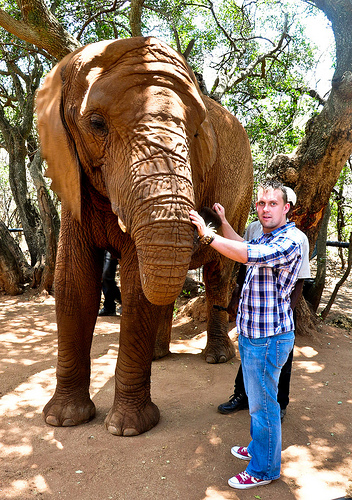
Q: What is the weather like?
A: It is clear.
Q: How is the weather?
A: It is clear.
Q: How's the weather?
A: It is clear.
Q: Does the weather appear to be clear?
A: Yes, it is clear.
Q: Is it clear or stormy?
A: It is clear.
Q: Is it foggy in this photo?
A: No, it is clear.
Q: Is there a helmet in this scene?
A: No, there are no helmets.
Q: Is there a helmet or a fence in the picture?
A: No, there are no helmets or fences.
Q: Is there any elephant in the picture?
A: Yes, there is an elephant.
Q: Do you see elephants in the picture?
A: Yes, there is an elephant.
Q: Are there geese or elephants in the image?
A: Yes, there is an elephant.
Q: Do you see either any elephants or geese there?
A: Yes, there is an elephant.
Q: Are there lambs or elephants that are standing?
A: Yes, the elephant is standing.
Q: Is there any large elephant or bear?
A: Yes, there is a large elephant.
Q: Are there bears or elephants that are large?
A: Yes, the elephant is large.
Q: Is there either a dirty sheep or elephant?
A: Yes, there is a dirty elephant.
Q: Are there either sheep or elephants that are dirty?
A: Yes, the elephant is dirty.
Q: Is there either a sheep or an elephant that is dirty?
A: Yes, the elephant is dirty.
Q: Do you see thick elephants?
A: Yes, there is a thick elephant.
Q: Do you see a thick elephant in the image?
A: Yes, there is a thick elephant.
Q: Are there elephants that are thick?
A: Yes, there is an elephant that is thick.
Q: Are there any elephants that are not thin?
A: Yes, there is a thick elephant.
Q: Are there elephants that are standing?
A: Yes, there is an elephant that is standing.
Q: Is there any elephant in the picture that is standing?
A: Yes, there is an elephant that is standing.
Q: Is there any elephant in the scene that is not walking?
A: Yes, there is an elephant that is standing.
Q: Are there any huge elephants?
A: Yes, there is a huge elephant.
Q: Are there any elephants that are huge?
A: Yes, there is an elephant that is huge.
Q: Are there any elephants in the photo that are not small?
A: Yes, there is a huge elephant.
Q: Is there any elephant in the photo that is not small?
A: Yes, there is a huge elephant.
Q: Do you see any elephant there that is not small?
A: Yes, there is a huge elephant.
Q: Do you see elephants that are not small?
A: Yes, there is a huge elephant.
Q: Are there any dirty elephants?
A: Yes, there is a dirty elephant.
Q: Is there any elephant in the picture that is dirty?
A: Yes, there is an elephant that is dirty.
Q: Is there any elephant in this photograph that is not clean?
A: Yes, there is a dirty elephant.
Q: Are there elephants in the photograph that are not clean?
A: Yes, there is a dirty elephant.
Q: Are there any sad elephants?
A: Yes, there is a sad elephant.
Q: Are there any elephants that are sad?
A: Yes, there is an elephant that is sad.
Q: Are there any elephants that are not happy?
A: Yes, there is a sad elephant.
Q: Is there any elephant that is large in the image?
A: Yes, there is a large elephant.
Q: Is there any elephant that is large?
A: Yes, there is an elephant that is large.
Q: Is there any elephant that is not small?
A: Yes, there is a large elephant.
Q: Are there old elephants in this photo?
A: Yes, there is an old elephant.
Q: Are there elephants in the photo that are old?
A: Yes, there is an elephant that is old.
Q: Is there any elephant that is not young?
A: Yes, there is a old elephant.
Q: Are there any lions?
A: No, there are no lions.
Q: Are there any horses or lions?
A: No, there are no lions or horses.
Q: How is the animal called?
A: The animal is an elephant.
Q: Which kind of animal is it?
A: The animal is an elephant.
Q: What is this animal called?
A: This is an elephant.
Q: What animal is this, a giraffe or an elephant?
A: This is an elephant.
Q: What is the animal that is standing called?
A: The animal is an elephant.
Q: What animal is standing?
A: The animal is an elephant.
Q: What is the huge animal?
A: The animal is an elephant.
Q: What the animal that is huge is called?
A: The animal is an elephant.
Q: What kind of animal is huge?
A: The animal is an elephant.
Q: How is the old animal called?
A: The animal is an elephant.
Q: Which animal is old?
A: The animal is an elephant.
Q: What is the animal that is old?
A: The animal is an elephant.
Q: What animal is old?
A: The animal is an elephant.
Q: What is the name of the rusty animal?
A: The animal is an elephant.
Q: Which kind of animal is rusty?
A: The animal is an elephant.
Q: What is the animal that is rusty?
A: The animal is an elephant.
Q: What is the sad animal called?
A: The animal is an elephant.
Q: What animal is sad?
A: The animal is an elephant.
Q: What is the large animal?
A: The animal is an elephant.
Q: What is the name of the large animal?
A: The animal is an elephant.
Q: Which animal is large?
A: The animal is an elephant.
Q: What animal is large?
A: The animal is an elephant.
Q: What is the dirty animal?
A: The animal is an elephant.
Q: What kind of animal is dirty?
A: The animal is an elephant.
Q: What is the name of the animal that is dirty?
A: The animal is an elephant.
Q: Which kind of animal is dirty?
A: The animal is an elephant.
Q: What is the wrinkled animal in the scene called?
A: The animal is an elephant.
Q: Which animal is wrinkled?
A: The animal is an elephant.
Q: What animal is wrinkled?
A: The animal is an elephant.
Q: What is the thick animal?
A: The animal is an elephant.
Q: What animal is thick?
A: The animal is an elephant.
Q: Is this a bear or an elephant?
A: This is an elephant.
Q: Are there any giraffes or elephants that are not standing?
A: No, there is an elephant but it is standing.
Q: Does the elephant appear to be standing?
A: Yes, the elephant is standing.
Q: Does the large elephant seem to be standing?
A: Yes, the elephant is standing.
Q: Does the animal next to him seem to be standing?
A: Yes, the elephant is standing.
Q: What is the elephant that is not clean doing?
A: The elephant is standing.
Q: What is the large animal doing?
A: The elephant is standing.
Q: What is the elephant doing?
A: The elephant is standing.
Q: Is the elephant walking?
A: No, the elephant is standing.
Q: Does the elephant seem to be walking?
A: No, the elephant is standing.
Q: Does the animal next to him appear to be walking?
A: No, the elephant is standing.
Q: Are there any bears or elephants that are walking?
A: No, there is an elephant but it is standing.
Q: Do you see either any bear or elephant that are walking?
A: No, there is an elephant but it is standing.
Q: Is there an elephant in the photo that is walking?
A: No, there is an elephant but it is standing.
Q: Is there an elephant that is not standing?
A: No, there is an elephant but it is standing.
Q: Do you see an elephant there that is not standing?
A: No, there is an elephant but it is standing.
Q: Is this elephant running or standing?
A: The elephant is standing.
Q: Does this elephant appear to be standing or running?
A: The elephant is standing.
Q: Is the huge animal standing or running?
A: The elephant is standing.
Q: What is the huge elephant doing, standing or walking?
A: The elephant is standing.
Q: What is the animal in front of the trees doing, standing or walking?
A: The elephant is standing.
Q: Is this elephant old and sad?
A: Yes, the elephant is old and sad.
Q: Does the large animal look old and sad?
A: Yes, the elephant is old and sad.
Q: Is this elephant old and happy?
A: No, the elephant is old but sad.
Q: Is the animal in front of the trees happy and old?
A: No, the elephant is old but sad.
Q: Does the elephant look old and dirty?
A: Yes, the elephant is old and dirty.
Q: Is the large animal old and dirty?
A: Yes, the elephant is old and dirty.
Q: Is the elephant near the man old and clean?
A: No, the elephant is old but dirty.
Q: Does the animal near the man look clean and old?
A: No, the elephant is old but dirty.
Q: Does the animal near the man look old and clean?
A: No, the elephant is old but dirty.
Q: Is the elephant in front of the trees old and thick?
A: Yes, the elephant is old and thick.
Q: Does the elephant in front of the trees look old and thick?
A: Yes, the elephant is old and thick.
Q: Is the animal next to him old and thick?
A: Yes, the elephant is old and thick.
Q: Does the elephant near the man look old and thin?
A: No, the elephant is old but thick.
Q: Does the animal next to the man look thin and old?
A: No, the elephant is old but thick.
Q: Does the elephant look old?
A: Yes, the elephant is old.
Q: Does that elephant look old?
A: Yes, the elephant is old.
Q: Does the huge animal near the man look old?
A: Yes, the elephant is old.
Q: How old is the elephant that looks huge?
A: The elephant is old.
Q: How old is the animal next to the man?
A: The elephant is old.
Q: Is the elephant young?
A: No, the elephant is old.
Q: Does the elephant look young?
A: No, the elephant is old.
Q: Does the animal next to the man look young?
A: No, the elephant is old.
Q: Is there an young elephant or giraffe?
A: No, there is an elephant but it is old.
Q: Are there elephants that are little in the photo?
A: No, there is an elephant but it is old.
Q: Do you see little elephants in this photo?
A: No, there is an elephant but it is old.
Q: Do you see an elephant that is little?
A: No, there is an elephant but it is old.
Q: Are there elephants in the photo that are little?
A: No, there is an elephant but it is old.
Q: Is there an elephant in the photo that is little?
A: No, there is an elephant but it is old.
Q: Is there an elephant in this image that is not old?
A: No, there is an elephant but it is old.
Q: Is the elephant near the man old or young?
A: The elephant is old.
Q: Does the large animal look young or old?
A: The elephant is old.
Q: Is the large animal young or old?
A: The elephant is old.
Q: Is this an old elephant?
A: Yes, this is an old elephant.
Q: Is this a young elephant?
A: No, this is an old elephant.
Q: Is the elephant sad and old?
A: Yes, the elephant is sad and old.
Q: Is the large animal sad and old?
A: Yes, the elephant is sad and old.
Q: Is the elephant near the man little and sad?
A: No, the elephant is sad but old.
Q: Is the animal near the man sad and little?
A: No, the elephant is sad but old.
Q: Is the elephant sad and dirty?
A: Yes, the elephant is sad and dirty.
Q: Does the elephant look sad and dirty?
A: Yes, the elephant is sad and dirty.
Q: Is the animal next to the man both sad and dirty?
A: Yes, the elephant is sad and dirty.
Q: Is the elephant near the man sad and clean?
A: No, the elephant is sad but dirty.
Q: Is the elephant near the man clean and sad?
A: No, the elephant is sad but dirty.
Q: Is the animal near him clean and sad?
A: No, the elephant is sad but dirty.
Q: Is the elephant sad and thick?
A: Yes, the elephant is sad and thick.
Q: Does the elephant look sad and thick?
A: Yes, the elephant is sad and thick.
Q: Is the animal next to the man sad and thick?
A: Yes, the elephant is sad and thick.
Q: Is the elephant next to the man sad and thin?
A: No, the elephant is sad but thick.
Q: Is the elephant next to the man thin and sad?
A: No, the elephant is sad but thick.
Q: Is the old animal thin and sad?
A: No, the elephant is sad but thick.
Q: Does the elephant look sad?
A: Yes, the elephant is sad.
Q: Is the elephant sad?
A: Yes, the elephant is sad.